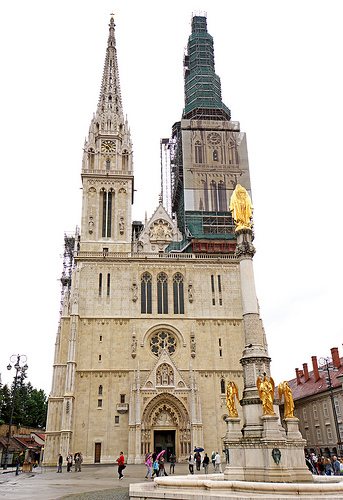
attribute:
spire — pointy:
[80, 11, 133, 177]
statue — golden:
[228, 182, 253, 231]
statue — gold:
[221, 379, 247, 419]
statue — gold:
[251, 370, 275, 417]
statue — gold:
[278, 380, 297, 423]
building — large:
[41, 10, 270, 465]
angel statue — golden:
[225, 380, 237, 422]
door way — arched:
[135, 383, 201, 456]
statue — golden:
[277, 379, 295, 417]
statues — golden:
[224, 377, 294, 419]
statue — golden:
[254, 369, 278, 417]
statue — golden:
[222, 377, 243, 418]